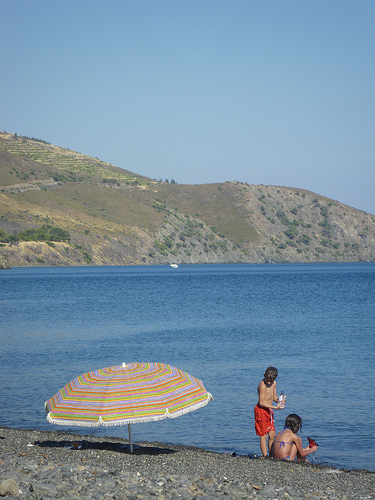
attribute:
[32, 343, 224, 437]
umbrella — beach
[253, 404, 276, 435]
shorts — red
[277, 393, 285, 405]
bottle — plastic, water bottle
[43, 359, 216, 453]
umrella — beach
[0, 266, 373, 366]
water — calm